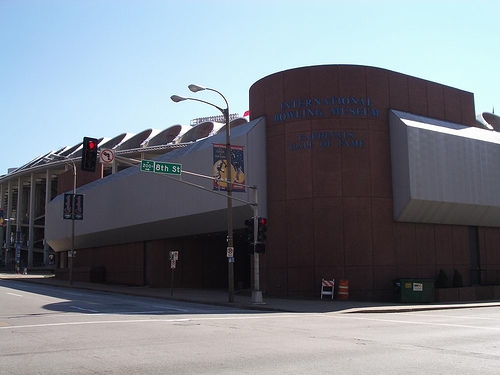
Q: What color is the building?
A: Brown.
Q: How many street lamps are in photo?
A: Two.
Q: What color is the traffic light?
A: Red.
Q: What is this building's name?
A: International Bowling Museum.